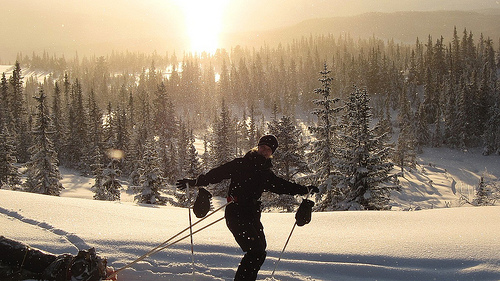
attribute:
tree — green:
[141, 127, 159, 205]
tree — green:
[128, 139, 169, 203]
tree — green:
[21, 88, 66, 194]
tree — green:
[327, 89, 400, 208]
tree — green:
[474, 175, 488, 204]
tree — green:
[88, 150, 110, 200]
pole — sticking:
[104, 196, 245, 278]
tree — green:
[303, 57, 351, 213]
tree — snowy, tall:
[305, 32, 394, 189]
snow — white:
[1, 187, 499, 273]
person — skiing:
[215, 117, 299, 278]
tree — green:
[23, 81, 65, 193]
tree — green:
[293, 59, 349, 209]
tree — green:
[137, 135, 168, 207]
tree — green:
[89, 145, 105, 199]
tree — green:
[333, 87, 402, 212]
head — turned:
[256, 132, 276, 158]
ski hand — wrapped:
[304, 174, 349, 196]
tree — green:
[82, 85, 112, 178]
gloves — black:
[173, 174, 201, 192]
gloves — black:
[304, 181, 321, 198]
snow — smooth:
[122, 219, 467, 273]